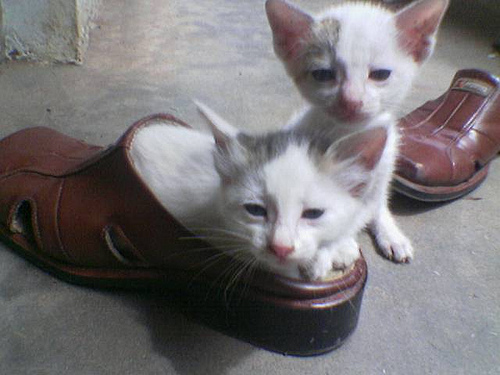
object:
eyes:
[243, 203, 267, 218]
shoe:
[392, 67, 500, 201]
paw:
[383, 244, 415, 264]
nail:
[389, 257, 392, 261]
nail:
[403, 258, 406, 263]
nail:
[408, 259, 413, 264]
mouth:
[345, 110, 359, 119]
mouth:
[278, 257, 288, 265]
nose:
[270, 244, 292, 256]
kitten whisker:
[164, 243, 244, 259]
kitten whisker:
[305, 259, 373, 317]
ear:
[320, 125, 389, 200]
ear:
[264, 0, 317, 53]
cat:
[261, 0, 450, 266]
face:
[283, 21, 416, 128]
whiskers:
[162, 219, 362, 321]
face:
[216, 154, 359, 269]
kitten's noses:
[339, 94, 364, 114]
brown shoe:
[0, 112, 368, 357]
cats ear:
[396, 0, 452, 66]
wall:
[0, 0, 71, 63]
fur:
[245, 133, 315, 162]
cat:
[130, 98, 389, 319]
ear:
[190, 98, 241, 157]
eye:
[301, 208, 326, 219]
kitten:
[129, 97, 396, 282]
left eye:
[367, 68, 391, 82]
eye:
[312, 66, 336, 83]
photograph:
[0, 0, 499, 375]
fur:
[301, 44, 331, 61]